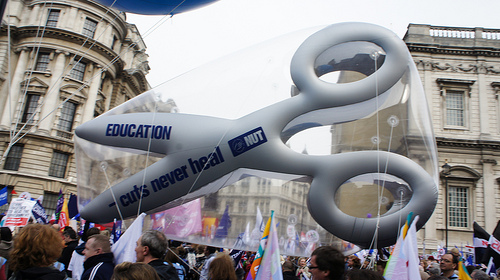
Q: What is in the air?
A: Scissors.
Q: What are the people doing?
A: Demonstrating.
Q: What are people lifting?
A: Flags.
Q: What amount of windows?
A: Ten.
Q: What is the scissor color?
A: Gray.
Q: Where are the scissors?
A: Bag.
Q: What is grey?
A: Scissors.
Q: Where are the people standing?
A: In the square.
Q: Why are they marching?
A: Parade.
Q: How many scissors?
A: One pair.